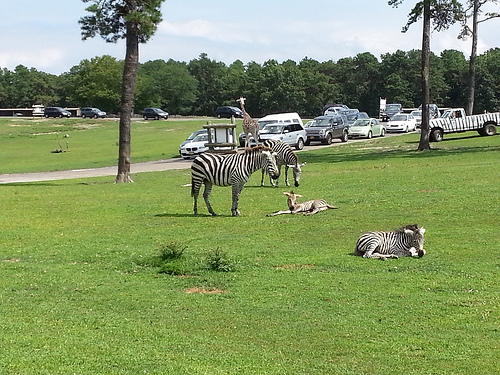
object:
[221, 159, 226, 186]
stripe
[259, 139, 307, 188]
zebra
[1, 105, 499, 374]
ground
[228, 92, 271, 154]
giraffe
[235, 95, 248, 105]
head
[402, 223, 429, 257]
head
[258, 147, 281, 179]
head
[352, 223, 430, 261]
zebra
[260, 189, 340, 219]
zebra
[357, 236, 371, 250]
stripe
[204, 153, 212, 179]
stripe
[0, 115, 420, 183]
path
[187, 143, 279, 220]
zebra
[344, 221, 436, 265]
adult zebras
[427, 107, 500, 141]
truck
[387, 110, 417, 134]
parked car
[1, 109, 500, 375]
zoo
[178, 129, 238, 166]
cars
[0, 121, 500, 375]
grass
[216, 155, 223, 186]
stripe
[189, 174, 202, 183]
stripe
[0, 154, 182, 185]
street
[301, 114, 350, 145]
car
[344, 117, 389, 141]
car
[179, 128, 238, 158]
car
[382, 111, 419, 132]
car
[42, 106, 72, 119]
car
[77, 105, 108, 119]
car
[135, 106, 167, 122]
car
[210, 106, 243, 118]
car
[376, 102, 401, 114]
car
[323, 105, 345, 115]
car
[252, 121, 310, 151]
car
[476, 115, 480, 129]
stripes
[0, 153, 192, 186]
path